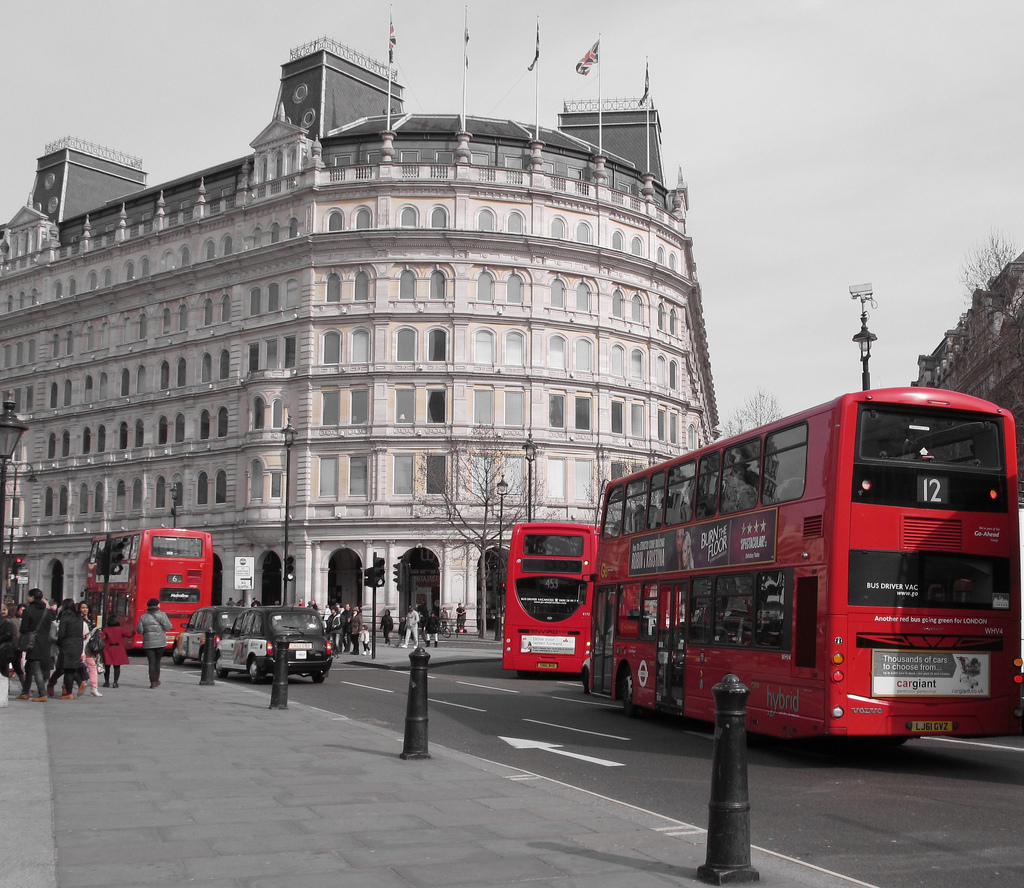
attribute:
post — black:
[382, 627, 499, 733]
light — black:
[321, 549, 430, 660]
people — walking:
[41, 586, 232, 686]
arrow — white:
[460, 698, 664, 815]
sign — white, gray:
[844, 627, 1007, 703]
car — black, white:
[187, 592, 404, 694]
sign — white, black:
[846, 631, 1017, 722]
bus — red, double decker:
[453, 420, 985, 749]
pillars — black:
[181, 616, 491, 764]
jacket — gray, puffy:
[120, 608, 187, 652]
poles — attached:
[315, 29, 665, 140]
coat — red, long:
[77, 625, 132, 675]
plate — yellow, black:
[872, 688, 1019, 769]